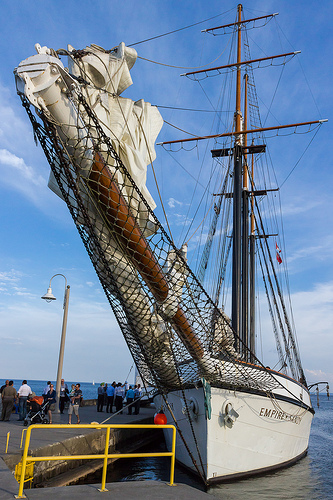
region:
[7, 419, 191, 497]
yellow metal guard railing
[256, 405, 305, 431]
writing on side of white boat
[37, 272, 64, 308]
white metal street light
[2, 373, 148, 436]
people standing on dock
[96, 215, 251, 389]
brown netting on front of boat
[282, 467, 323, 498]
small ripples on surface of water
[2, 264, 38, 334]
small clouds in blue sky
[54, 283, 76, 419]
large metal street light pole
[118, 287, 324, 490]
large white docked boat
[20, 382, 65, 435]
woman pushing stroller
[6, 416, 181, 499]
yellow railing made of metal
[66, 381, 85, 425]
person walking on a wooden pier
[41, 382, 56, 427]
person walking on a wooden pier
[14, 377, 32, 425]
person standing on a wooden pier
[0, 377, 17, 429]
person standing on a wooden pier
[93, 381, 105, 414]
person standing on a wooden pier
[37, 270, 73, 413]
street light on a large wooden pole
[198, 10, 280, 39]
wooden crossbeam on a sailboat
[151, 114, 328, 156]
wooden crossbeam on a sailboat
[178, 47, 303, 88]
wooden crossbeam on a sailboat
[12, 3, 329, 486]
the large boat on the water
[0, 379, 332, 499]
the body of water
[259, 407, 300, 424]
the letters on the boat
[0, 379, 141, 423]
the people on the dock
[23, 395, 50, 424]
the stroller on the dock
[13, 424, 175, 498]
the yellow railing near the water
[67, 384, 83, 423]
the man carrying the small child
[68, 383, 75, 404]
the small child being carried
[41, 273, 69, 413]
the light post on the dock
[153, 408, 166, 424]
the buoy on the boat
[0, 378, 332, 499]
a large body of water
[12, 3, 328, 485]
a large boat in the water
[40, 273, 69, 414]
a light pole on the dock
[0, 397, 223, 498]
a large concrete dock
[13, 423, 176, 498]
a yellow metal railing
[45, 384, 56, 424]
a woman pushing a stroller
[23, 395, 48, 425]
a stroller being pushed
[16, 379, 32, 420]
a man on the dock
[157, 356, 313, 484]
white boat in water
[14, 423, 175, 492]
yellow safety railing on dock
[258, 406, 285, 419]
empire written on side of boat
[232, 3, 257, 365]
wood and metal sail mast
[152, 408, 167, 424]
red buoy hanging from boat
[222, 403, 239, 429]
white anchor hanging from boat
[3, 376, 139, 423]
people walking on dock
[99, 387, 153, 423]
rope used to moor boat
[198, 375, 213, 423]
green flag on front of boat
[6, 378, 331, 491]
blue water of ocean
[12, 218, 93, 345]
blue and white sky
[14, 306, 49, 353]
white clouds in sky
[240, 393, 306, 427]
black lettering on boat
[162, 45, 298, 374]
bare sail on boat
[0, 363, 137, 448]
people walking on pier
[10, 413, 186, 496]
yellow rail near boat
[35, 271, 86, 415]
light post near people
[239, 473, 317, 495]
small ripples on water